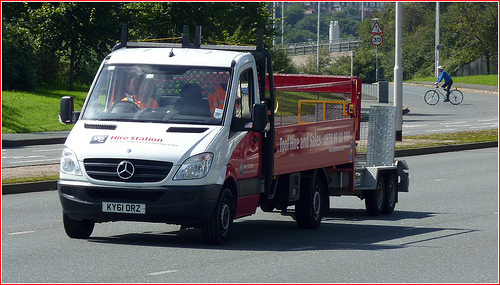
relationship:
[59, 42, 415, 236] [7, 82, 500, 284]
truck riding down street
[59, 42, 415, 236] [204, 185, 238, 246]
truck has tire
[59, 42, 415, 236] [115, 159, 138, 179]
truck has emblem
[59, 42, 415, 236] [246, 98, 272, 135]
truck has side mirror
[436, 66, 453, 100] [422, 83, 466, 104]
person riding bike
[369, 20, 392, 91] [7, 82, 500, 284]
sign on side of road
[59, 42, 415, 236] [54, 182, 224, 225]
truck has bumper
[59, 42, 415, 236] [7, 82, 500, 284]
truck driving on street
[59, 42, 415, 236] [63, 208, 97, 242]
truck has tire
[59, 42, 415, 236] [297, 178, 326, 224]
truck has tire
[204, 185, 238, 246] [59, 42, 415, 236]
tire on side of truck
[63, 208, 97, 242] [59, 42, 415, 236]
tire on side of truck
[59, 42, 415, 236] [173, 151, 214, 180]
truck has headlight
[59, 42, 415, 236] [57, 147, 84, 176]
truck has headlight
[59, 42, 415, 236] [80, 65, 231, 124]
truck has windshield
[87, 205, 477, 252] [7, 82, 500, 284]
shade on street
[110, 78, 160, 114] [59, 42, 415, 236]
man driving truck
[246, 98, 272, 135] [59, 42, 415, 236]
side mirror on truck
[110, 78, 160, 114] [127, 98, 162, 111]
man wearing shirt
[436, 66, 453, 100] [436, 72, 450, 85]
person wearing shirt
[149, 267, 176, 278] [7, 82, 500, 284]
line painted on road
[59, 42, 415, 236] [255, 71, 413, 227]
truck pulling trailer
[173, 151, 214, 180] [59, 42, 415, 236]
headlight on truck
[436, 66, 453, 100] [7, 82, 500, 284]
person on street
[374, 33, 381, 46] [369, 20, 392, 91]
30 written on sign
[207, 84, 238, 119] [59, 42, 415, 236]
safety jacket in truck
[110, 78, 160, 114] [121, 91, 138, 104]
man wearing seat belt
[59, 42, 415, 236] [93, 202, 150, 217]
truck has license plate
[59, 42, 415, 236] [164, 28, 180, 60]
truck has antenna